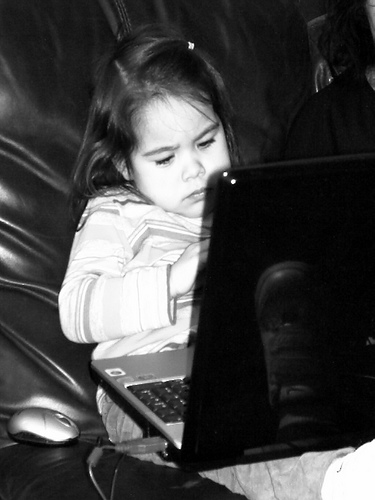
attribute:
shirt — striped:
[59, 190, 208, 361]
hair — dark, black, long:
[76, 23, 231, 207]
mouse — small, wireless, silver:
[3, 408, 82, 446]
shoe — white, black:
[327, 441, 375, 499]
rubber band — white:
[186, 39, 197, 51]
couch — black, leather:
[3, 4, 357, 329]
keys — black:
[134, 374, 191, 425]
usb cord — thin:
[84, 446, 108, 499]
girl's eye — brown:
[151, 150, 176, 167]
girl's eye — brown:
[195, 138, 216, 148]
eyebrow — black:
[139, 147, 185, 155]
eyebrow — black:
[191, 125, 226, 140]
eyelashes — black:
[156, 157, 173, 162]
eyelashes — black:
[199, 142, 212, 147]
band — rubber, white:
[189, 37, 197, 52]